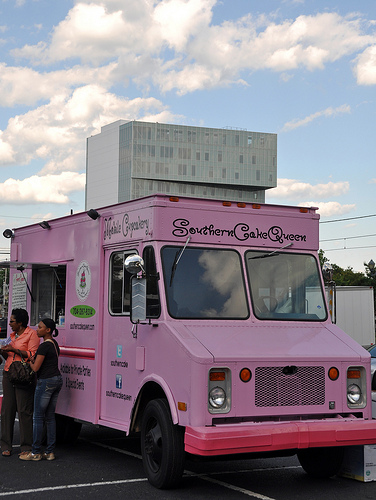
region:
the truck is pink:
[147, 281, 235, 407]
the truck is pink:
[130, 370, 188, 459]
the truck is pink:
[165, 372, 216, 472]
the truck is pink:
[199, 394, 252, 496]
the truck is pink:
[187, 346, 245, 459]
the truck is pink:
[184, 370, 229, 479]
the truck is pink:
[84, 230, 265, 395]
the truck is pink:
[179, 341, 212, 416]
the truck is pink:
[160, 343, 248, 493]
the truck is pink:
[157, 246, 302, 492]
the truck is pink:
[120, 275, 230, 462]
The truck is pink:
[12, 226, 359, 476]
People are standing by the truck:
[7, 301, 74, 467]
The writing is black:
[146, 209, 306, 249]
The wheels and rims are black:
[122, 395, 182, 491]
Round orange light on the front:
[236, 361, 261, 385]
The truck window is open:
[7, 239, 91, 346]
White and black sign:
[6, 264, 41, 335]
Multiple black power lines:
[314, 210, 370, 275]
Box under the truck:
[333, 443, 371, 492]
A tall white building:
[80, 119, 305, 218]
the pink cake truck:
[7, 197, 374, 484]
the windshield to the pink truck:
[158, 239, 325, 321]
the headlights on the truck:
[206, 362, 363, 410]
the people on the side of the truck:
[2, 303, 56, 458]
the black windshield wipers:
[166, 234, 290, 282]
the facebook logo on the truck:
[113, 371, 119, 384]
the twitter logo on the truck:
[114, 342, 118, 355]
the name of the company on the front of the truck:
[168, 213, 305, 237]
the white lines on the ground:
[17, 476, 127, 495]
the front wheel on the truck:
[139, 396, 181, 484]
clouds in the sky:
[62, 0, 182, 118]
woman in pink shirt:
[2, 302, 39, 488]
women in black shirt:
[7, 313, 92, 466]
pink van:
[8, 186, 374, 482]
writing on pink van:
[163, 194, 334, 241]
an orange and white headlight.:
[195, 361, 239, 418]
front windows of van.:
[150, 224, 332, 333]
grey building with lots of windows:
[68, 115, 294, 207]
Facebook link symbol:
[104, 371, 132, 406]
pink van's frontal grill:
[249, 360, 334, 418]